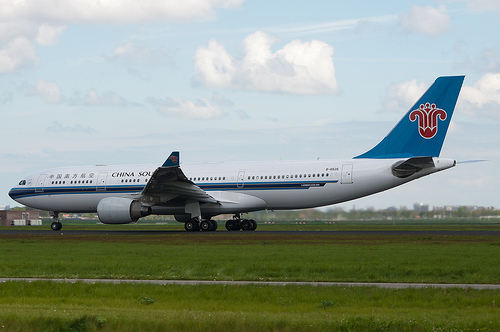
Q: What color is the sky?
A: Blue.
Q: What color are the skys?
A: White.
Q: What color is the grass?
A: Green.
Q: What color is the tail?
A: Blue.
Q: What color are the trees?
A: Green.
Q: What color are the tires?
A: Black.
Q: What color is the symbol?
A: Red.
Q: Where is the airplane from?
A: China.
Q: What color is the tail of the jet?
A: Blue.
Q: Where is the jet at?
A: On the runway.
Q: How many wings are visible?
A: One.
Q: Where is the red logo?
A: On the plane's tail.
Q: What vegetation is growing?
A: Grass.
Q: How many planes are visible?
A: One.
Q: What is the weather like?
A: Partly cloudy.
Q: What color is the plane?
A: White and blue.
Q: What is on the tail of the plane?
A: A symbol.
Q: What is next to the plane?
A: The grass.